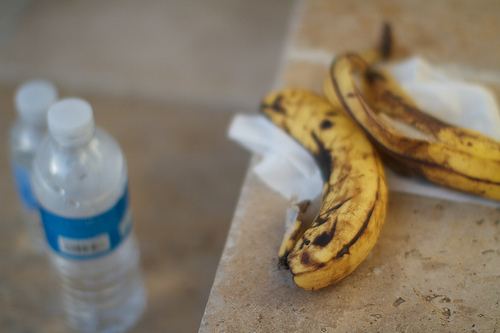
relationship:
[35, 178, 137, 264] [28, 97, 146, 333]
label on water bottle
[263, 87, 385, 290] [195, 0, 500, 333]
banana on counter top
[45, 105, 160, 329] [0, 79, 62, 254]
water bottle next to bottle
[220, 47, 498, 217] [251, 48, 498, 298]
napkin under bananas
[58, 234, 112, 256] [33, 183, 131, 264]
bar code on label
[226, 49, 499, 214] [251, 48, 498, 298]
bag beneath bananas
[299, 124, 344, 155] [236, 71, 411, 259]
bruise on left banana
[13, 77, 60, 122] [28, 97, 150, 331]
cap on top fo bottle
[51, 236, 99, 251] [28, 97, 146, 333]
bar code on water bottle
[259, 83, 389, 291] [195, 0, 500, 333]
banana on counter top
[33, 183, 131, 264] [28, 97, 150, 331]
label on bottle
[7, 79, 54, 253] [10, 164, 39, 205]
bottle with label